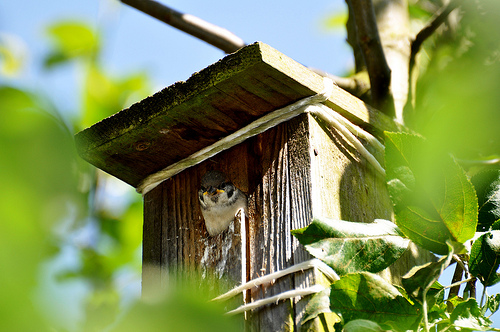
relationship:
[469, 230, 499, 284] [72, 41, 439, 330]
leaf touching bird house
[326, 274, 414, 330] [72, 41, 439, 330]
leaf touching bird house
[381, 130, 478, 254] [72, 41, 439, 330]
leaf touching bird house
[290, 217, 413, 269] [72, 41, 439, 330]
leaf touching bird house